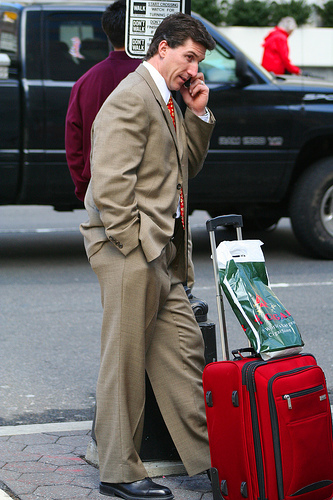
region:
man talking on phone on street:
[84, 15, 231, 498]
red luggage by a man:
[197, 338, 330, 498]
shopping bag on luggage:
[208, 227, 309, 368]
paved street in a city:
[9, 282, 84, 406]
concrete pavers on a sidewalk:
[10, 435, 73, 498]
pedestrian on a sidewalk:
[263, 14, 307, 76]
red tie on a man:
[163, 99, 182, 135]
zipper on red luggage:
[278, 389, 293, 410]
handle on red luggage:
[201, 210, 249, 231]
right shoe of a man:
[88, 468, 185, 497]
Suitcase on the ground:
[202, 210, 330, 497]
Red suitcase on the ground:
[200, 212, 331, 498]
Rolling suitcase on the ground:
[201, 211, 331, 497]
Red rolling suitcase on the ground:
[199, 210, 330, 497]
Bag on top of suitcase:
[206, 235, 308, 361]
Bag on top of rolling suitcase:
[205, 236, 305, 362]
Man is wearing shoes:
[89, 469, 234, 499]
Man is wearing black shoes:
[96, 466, 214, 497]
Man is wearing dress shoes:
[96, 467, 224, 498]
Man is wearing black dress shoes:
[95, 467, 219, 498]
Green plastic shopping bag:
[212, 238, 304, 359]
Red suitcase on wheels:
[199, 213, 331, 499]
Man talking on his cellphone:
[78, 11, 217, 499]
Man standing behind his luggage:
[80, 12, 331, 499]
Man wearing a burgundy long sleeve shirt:
[63, 0, 193, 288]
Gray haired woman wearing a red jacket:
[258, 15, 298, 75]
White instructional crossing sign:
[123, 0, 187, 61]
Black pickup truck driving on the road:
[0, 0, 332, 261]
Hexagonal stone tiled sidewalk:
[0, 427, 214, 498]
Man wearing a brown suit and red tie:
[80, 13, 214, 498]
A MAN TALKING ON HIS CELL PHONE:
[78, 9, 217, 496]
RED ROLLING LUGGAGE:
[199, 211, 329, 495]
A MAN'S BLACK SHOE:
[93, 475, 176, 497]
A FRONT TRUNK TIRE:
[286, 154, 329, 265]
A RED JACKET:
[256, 24, 303, 79]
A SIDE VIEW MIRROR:
[228, 53, 258, 87]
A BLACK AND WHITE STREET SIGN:
[121, 2, 188, 62]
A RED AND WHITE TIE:
[164, 98, 191, 235]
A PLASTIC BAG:
[212, 233, 308, 366]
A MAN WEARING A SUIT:
[77, 8, 218, 497]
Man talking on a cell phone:
[75, 8, 226, 497]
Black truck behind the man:
[2, 1, 331, 261]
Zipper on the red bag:
[277, 388, 297, 413]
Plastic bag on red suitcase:
[196, 212, 331, 497]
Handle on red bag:
[201, 209, 267, 361]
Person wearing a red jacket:
[259, 9, 307, 80]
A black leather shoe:
[95, 473, 173, 497]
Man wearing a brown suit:
[75, 12, 229, 484]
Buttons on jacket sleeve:
[103, 228, 128, 259]